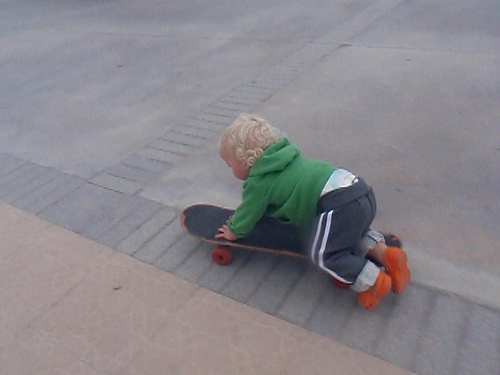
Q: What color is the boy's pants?
A: Gray and white.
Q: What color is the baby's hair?
A: Blonde.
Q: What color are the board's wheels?
A: Red.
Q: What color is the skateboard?
A: Black.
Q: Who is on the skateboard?
A: A baby.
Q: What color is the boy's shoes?
A: Orange.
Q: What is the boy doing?
A: Riding a skateboard.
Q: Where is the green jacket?
A: On the baby.